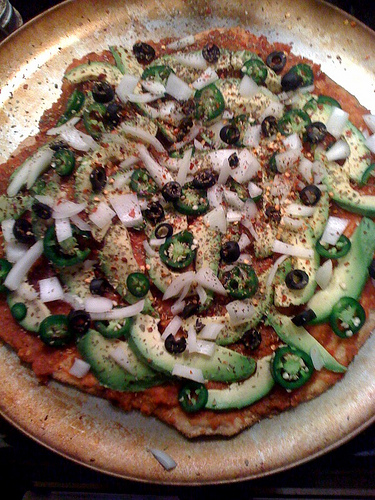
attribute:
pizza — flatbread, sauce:
[18, 17, 321, 480]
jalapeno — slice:
[253, 340, 327, 396]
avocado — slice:
[195, 345, 294, 419]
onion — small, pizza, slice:
[299, 254, 353, 304]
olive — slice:
[290, 267, 302, 285]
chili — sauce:
[8, 330, 82, 392]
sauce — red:
[40, 83, 81, 145]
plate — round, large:
[7, 9, 102, 108]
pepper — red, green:
[102, 170, 169, 251]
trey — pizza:
[13, 9, 82, 88]